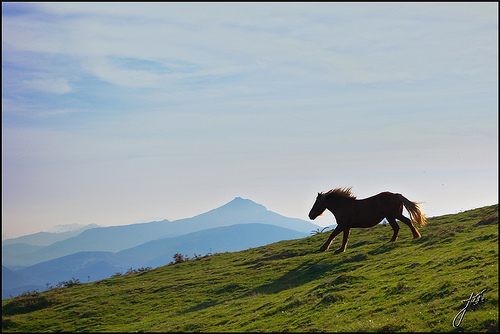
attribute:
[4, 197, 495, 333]
field — lush, green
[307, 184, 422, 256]
horse — running, brown, galloping, free, elegant, attractive, amazing, beautiful, healthy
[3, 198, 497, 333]
hill — grassy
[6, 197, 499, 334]
grass — green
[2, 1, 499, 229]
sky — beautiful